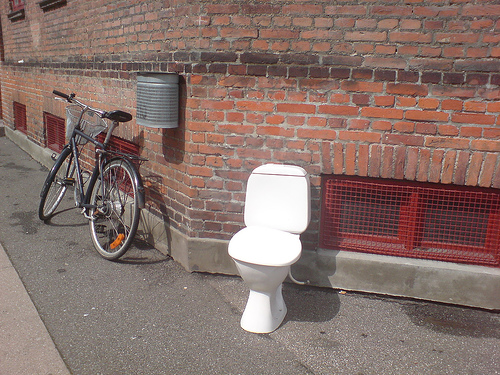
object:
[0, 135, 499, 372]
street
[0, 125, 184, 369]
sidewalk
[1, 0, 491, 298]
building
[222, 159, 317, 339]
toilet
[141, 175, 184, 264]
shadow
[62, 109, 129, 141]
basket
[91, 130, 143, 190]
panes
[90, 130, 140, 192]
window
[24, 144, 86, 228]
wheel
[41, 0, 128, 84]
wall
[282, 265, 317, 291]
tube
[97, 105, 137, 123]
seat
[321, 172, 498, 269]
grates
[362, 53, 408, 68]
bricks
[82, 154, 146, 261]
back wheel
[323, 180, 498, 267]
red cover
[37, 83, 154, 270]
bicycle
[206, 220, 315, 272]
cover